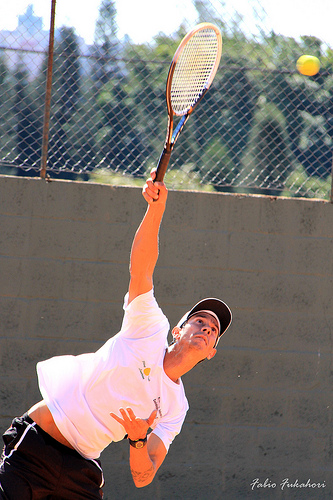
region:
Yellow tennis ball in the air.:
[296, 52, 320, 76]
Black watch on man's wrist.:
[126, 435, 147, 449]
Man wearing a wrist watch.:
[127, 435, 147, 448]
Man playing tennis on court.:
[0, 21, 331, 499]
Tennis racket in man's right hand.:
[142, 22, 221, 205]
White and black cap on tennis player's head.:
[175, 296, 232, 347]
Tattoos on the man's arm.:
[130, 465, 157, 487]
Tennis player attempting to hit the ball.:
[0, 21, 332, 499]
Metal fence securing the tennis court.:
[0, 1, 332, 198]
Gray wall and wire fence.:
[1, 0, 331, 496]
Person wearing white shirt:
[81, 379, 169, 465]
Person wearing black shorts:
[18, 404, 69, 492]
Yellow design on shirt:
[139, 362, 161, 388]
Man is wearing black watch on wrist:
[120, 424, 177, 484]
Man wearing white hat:
[173, 290, 258, 379]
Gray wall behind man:
[251, 334, 325, 484]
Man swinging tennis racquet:
[155, 36, 238, 171]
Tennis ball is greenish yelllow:
[281, 41, 329, 110]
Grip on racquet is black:
[143, 145, 185, 197]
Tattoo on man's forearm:
[124, 459, 180, 499]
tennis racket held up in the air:
[126, 12, 237, 219]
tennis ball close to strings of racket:
[157, 23, 328, 127]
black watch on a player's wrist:
[97, 402, 166, 454]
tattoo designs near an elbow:
[123, 459, 166, 485]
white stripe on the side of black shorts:
[1, 405, 40, 481]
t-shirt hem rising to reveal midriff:
[14, 350, 88, 457]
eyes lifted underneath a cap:
[170, 284, 244, 375]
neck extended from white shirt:
[156, 328, 203, 390]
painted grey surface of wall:
[47, 206, 301, 451]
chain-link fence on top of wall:
[6, 59, 125, 223]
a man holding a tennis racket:
[0, 19, 248, 495]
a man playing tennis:
[69, 10, 243, 495]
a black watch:
[120, 425, 168, 460]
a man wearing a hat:
[151, 278, 250, 397]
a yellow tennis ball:
[288, 43, 321, 89]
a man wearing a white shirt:
[27, 249, 268, 491]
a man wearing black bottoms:
[8, 307, 251, 498]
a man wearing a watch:
[73, 289, 232, 480]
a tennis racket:
[121, 24, 277, 232]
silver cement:
[1, 168, 326, 495]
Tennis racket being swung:
[153, 21, 224, 194]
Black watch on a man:
[128, 436, 148, 448]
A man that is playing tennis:
[7, 164, 232, 498]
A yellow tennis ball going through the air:
[296, 56, 321, 77]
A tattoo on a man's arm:
[127, 461, 157, 481]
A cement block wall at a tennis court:
[0, 172, 330, 497]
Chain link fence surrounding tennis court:
[11, 0, 142, 173]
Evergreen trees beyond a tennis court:
[210, 92, 328, 178]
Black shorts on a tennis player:
[0, 412, 104, 499]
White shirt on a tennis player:
[37, 288, 197, 454]